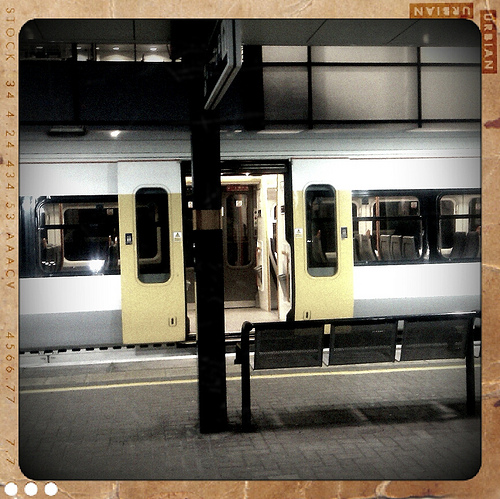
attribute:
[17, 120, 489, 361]
car — silver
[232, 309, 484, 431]
bench — steel, vacant, black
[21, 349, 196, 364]
beam — metal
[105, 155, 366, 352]
door — open, yellow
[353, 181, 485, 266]
window — glass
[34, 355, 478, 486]
tile — gray, rectangular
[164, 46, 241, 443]
pole — metal, black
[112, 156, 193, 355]
door — open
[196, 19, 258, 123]
sign — white, stop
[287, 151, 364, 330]
door is — open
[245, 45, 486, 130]
frame — brown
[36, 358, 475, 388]
line — yellow